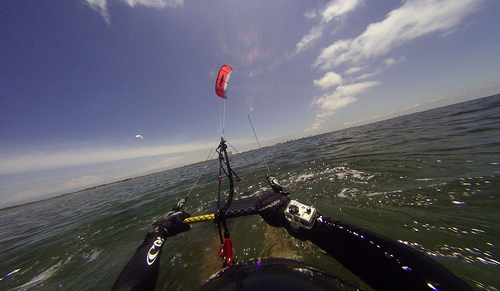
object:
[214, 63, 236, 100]
kite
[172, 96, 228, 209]
ropes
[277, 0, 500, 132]
clouds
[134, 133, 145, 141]
kite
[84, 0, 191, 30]
clouds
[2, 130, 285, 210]
clouds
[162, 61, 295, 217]
parachute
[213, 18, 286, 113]
light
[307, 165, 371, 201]
foam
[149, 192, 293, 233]
handles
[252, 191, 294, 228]
glove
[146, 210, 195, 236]
glove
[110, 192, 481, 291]
person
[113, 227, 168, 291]
left arm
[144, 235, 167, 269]
harness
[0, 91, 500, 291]
water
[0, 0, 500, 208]
sky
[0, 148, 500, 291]
wave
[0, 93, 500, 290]
ocean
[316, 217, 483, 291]
arms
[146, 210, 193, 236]
hand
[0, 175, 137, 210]
land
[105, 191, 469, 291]
wetsuit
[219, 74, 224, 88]
spot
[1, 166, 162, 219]
background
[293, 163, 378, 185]
tops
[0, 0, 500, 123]
air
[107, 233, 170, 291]
arm